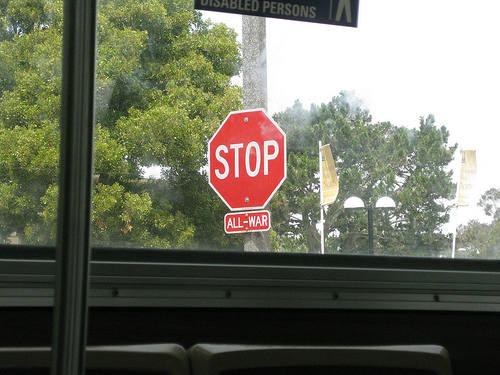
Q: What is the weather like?
A: It is overcast.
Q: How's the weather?
A: It is overcast.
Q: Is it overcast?
A: Yes, it is overcast.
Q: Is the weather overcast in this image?
A: Yes, it is overcast.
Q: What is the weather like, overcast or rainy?
A: It is overcast.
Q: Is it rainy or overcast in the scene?
A: It is overcast.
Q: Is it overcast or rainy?
A: It is overcast.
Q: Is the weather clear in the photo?
A: No, it is overcast.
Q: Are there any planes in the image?
A: No, there are no planes.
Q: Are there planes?
A: No, there are no planes.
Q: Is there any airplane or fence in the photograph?
A: No, there are no airplanes or fences.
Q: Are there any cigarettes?
A: No, there are no cigarettes.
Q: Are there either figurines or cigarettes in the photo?
A: No, there are no cigarettes or figurines.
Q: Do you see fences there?
A: No, there are no fences.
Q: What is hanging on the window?
A: The sign is hanging on the window.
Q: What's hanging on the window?
A: The sign is hanging on the window.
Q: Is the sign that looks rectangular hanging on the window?
A: Yes, the sign is hanging on the window.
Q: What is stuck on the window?
A: The sign is stuck on the window.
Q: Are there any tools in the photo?
A: No, there are no tools.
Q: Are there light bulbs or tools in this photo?
A: No, there are no tools or light bulbs.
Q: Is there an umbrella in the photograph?
A: No, there are no umbrellas.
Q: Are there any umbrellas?
A: No, there are no umbrellas.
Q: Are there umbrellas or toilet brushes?
A: No, there are no umbrellas or toilet brushes.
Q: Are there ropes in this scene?
A: No, there are no ropes.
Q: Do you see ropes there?
A: No, there are no ropes.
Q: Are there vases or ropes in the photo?
A: No, there are no ropes or vases.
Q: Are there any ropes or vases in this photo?
A: No, there are no ropes or vases.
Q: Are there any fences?
A: No, there are no fences.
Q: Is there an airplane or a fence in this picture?
A: No, there are no fences or airplanes.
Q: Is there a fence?
A: No, there are no fences.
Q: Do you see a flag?
A: Yes, there is a flag.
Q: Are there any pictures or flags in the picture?
A: Yes, there is a flag.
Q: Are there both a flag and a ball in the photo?
A: No, there is a flag but no balls.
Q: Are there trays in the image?
A: No, there are no trays.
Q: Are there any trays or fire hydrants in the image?
A: No, there are no trays or fire hydrants.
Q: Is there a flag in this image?
A: Yes, there is a flag.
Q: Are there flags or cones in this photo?
A: Yes, there is a flag.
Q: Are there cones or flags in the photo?
A: Yes, there is a flag.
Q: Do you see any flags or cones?
A: Yes, there is a flag.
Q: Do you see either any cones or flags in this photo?
A: Yes, there is a flag.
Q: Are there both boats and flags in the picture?
A: No, there is a flag but no boats.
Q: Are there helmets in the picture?
A: No, there are no helmets.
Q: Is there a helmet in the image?
A: No, there are no helmets.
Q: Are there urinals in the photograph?
A: No, there are no urinals.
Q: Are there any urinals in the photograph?
A: No, there are no urinals.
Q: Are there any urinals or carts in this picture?
A: No, there are no urinals or carts.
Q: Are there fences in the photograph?
A: No, there are no fences.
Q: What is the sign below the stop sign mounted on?
A: The sign is mounted on the pole.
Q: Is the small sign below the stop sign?
A: Yes, the sign is below the stop sign.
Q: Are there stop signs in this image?
A: Yes, there is a stop sign.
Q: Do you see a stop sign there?
A: Yes, there is a stop sign.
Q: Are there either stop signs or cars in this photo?
A: Yes, there is a stop sign.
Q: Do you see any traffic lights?
A: No, there are no traffic lights.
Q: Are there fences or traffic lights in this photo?
A: No, there are no traffic lights or fences.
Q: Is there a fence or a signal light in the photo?
A: No, there are no traffic lights or fences.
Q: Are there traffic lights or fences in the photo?
A: No, there are no traffic lights or fences.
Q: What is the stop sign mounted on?
A: The stop sign is mounted on the pole.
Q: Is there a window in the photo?
A: Yes, there is a window.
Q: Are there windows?
A: Yes, there is a window.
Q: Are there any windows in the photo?
A: Yes, there is a window.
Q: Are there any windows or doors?
A: Yes, there is a window.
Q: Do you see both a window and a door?
A: No, there is a window but no doors.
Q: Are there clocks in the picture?
A: No, there are no clocks.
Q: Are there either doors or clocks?
A: No, there are no clocks or doors.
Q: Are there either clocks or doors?
A: No, there are no clocks or doors.